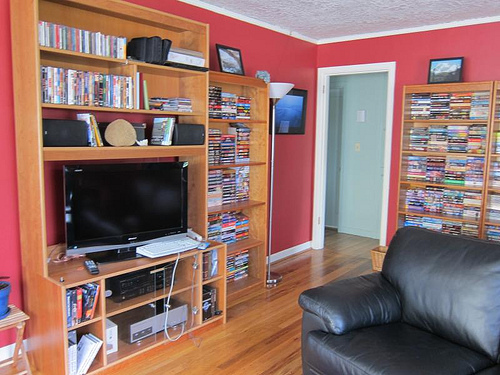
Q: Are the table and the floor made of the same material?
A: Yes, both the table and the floor are made of wood.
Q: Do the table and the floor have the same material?
A: Yes, both the table and the floor are made of wood.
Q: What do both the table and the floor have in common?
A: The material, both the table and the floor are wooden.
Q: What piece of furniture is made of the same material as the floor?
A: The table is made of the same material as the floor.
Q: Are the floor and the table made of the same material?
A: Yes, both the floor and the table are made of wood.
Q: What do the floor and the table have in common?
A: The material, both the floor and the table are wooden.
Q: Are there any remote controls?
A: Yes, there is a remote control.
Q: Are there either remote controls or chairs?
A: Yes, there is a remote control.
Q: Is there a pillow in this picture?
A: No, there are no pillows.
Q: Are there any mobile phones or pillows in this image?
A: No, there are no pillows or mobile phones.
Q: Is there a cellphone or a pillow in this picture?
A: No, there are no pillows or cell phones.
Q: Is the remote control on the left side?
A: Yes, the remote control is on the left of the image.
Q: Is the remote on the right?
A: No, the remote is on the left of the image.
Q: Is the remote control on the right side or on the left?
A: The remote control is on the left of the image.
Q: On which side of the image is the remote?
A: The remote is on the left of the image.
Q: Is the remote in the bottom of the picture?
A: Yes, the remote is in the bottom of the image.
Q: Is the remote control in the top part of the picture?
A: No, the remote control is in the bottom of the image.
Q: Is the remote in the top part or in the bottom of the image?
A: The remote is in the bottom of the image.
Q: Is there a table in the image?
A: Yes, there is a table.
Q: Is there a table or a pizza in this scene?
A: Yes, there is a table.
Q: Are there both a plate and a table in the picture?
A: No, there is a table but no plates.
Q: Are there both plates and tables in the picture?
A: No, there is a table but no plates.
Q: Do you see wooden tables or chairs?
A: Yes, there is a wood table.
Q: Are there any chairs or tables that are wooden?
A: Yes, the table is wooden.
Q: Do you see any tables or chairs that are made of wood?
A: Yes, the table is made of wood.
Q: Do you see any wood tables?
A: Yes, there is a wood table.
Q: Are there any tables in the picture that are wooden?
A: Yes, there is a table that is wooden.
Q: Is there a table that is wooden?
A: Yes, there is a table that is wooden.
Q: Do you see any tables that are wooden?
A: Yes, there is a table that is wooden.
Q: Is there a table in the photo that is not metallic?
A: Yes, there is a wooden table.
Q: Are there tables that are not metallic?
A: Yes, there is a wooden table.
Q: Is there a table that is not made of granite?
A: Yes, there is a table that is made of wood.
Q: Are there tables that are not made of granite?
A: Yes, there is a table that is made of wood.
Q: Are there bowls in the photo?
A: No, there are no bowls.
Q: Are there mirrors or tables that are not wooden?
A: No, there is a table but it is wooden.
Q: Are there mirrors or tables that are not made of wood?
A: No, there is a table but it is made of wood.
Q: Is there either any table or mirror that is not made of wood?
A: No, there is a table but it is made of wood.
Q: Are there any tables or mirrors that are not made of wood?
A: No, there is a table but it is made of wood.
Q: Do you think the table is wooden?
A: Yes, the table is wooden.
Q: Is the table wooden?
A: Yes, the table is wooden.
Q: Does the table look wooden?
A: Yes, the table is wooden.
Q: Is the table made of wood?
A: Yes, the table is made of wood.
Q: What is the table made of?
A: The table is made of wood.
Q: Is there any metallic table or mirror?
A: No, there is a table but it is wooden.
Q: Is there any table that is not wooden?
A: No, there is a table but it is wooden.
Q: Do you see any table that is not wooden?
A: No, there is a table but it is wooden.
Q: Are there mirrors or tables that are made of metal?
A: No, there is a table but it is made of wood.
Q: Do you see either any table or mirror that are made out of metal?
A: No, there is a table but it is made of wood.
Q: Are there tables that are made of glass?
A: No, there is a table but it is made of wood.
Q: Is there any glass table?
A: No, there is a table but it is made of wood.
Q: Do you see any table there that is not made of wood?
A: No, there is a table but it is made of wood.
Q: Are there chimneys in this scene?
A: No, there are no chimneys.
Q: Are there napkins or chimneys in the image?
A: No, there are no chimneys or napkins.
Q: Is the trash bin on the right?
A: Yes, the trash bin is on the right of the image.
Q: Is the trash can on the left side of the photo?
A: No, the trash can is on the right of the image.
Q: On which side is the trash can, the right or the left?
A: The trash can is on the right of the image.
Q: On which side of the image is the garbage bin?
A: The garbage bin is on the right of the image.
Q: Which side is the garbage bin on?
A: The garbage bin is on the right of the image.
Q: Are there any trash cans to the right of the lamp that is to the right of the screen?
A: Yes, there is a trash can to the right of the lamp.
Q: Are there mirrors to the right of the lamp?
A: No, there is a trash can to the right of the lamp.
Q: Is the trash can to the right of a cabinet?
A: No, the trash can is to the right of the lamp.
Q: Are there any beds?
A: No, there are no beds.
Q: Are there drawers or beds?
A: No, there are no beds or drawers.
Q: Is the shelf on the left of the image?
A: Yes, the shelf is on the left of the image.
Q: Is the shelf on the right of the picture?
A: No, the shelf is on the left of the image.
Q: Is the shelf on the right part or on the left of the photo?
A: The shelf is on the left of the image.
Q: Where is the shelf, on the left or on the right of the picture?
A: The shelf is on the left of the image.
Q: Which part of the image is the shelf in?
A: The shelf is on the left of the image.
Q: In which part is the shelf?
A: The shelf is on the left of the image.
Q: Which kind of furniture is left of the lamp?
A: The piece of furniture is a shelf.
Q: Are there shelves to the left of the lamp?
A: Yes, there is a shelf to the left of the lamp.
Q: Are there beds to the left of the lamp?
A: No, there is a shelf to the left of the lamp.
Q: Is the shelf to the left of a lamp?
A: Yes, the shelf is to the left of a lamp.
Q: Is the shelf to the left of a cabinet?
A: No, the shelf is to the left of a lamp.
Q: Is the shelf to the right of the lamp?
A: No, the shelf is to the left of the lamp.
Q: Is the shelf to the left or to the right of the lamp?
A: The shelf is to the left of the lamp.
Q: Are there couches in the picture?
A: Yes, there is a couch.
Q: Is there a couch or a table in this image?
A: Yes, there is a couch.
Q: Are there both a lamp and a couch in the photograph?
A: Yes, there are both a couch and a lamp.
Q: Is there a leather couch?
A: Yes, there is a couch that is made of leather.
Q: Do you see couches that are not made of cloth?
A: Yes, there is a couch that is made of leather.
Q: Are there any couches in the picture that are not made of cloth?
A: Yes, there is a couch that is made of leather.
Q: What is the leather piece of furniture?
A: The piece of furniture is a couch.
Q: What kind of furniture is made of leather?
A: The furniture is a couch.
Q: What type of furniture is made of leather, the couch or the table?
A: The couch is made of leather.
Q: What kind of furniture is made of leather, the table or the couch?
A: The couch is made of leather.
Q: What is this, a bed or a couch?
A: This is a couch.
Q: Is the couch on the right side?
A: Yes, the couch is on the right of the image.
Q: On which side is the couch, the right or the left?
A: The couch is on the right of the image.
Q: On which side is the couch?
A: The couch is on the right of the image.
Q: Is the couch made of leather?
A: Yes, the couch is made of leather.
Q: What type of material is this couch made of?
A: The couch is made of leather.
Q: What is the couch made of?
A: The couch is made of leather.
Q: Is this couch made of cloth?
A: No, the couch is made of leather.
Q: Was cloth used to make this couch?
A: No, the couch is made of leather.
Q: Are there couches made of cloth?
A: No, there is a couch but it is made of leather.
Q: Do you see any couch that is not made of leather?
A: No, there is a couch but it is made of leather.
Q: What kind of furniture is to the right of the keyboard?
A: The piece of furniture is a couch.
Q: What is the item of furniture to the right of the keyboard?
A: The piece of furniture is a couch.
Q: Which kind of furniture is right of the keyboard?
A: The piece of furniture is a couch.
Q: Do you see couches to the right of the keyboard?
A: Yes, there is a couch to the right of the keyboard.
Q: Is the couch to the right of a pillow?
A: No, the couch is to the right of the keyboard.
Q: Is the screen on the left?
A: Yes, the screen is on the left of the image.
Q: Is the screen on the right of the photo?
A: No, the screen is on the left of the image.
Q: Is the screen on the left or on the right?
A: The screen is on the left of the image.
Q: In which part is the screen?
A: The screen is on the left of the image.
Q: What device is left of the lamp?
A: The device is a screen.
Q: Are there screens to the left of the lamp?
A: Yes, there is a screen to the left of the lamp.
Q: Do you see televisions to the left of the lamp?
A: No, there is a screen to the left of the lamp.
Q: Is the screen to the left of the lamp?
A: Yes, the screen is to the left of the lamp.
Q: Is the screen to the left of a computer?
A: No, the screen is to the left of the lamp.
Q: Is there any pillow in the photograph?
A: No, there are no pillows.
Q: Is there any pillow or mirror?
A: No, there are no pillows or mirrors.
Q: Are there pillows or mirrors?
A: No, there are no pillows or mirrors.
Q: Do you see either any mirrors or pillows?
A: No, there are no pillows or mirrors.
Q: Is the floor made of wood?
A: Yes, the floor is made of wood.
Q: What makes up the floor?
A: The floor is made of wood.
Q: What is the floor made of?
A: The floor is made of wood.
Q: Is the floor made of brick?
A: No, the floor is made of wood.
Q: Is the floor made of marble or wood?
A: The floor is made of wood.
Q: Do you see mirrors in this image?
A: No, there are no mirrors.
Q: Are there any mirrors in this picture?
A: No, there are no mirrors.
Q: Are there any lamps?
A: Yes, there is a lamp.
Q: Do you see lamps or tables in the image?
A: Yes, there is a lamp.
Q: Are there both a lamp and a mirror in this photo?
A: No, there is a lamp but no mirrors.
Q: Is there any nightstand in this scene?
A: No, there are no nightstands.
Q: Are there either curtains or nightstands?
A: No, there are no nightstands or curtains.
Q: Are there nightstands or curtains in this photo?
A: No, there are no nightstands or curtains.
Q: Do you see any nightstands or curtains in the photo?
A: No, there are no nightstands or curtains.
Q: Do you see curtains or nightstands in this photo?
A: No, there are no nightstands or curtains.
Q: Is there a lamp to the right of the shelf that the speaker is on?
A: Yes, there is a lamp to the right of the shelf.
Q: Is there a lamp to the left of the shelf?
A: No, the lamp is to the right of the shelf.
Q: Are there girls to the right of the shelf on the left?
A: No, there is a lamp to the right of the shelf.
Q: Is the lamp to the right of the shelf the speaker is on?
A: Yes, the lamp is to the right of the shelf.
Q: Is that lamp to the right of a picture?
A: No, the lamp is to the right of the shelf.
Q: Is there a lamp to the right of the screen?
A: Yes, there is a lamp to the right of the screen.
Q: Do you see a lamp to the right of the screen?
A: Yes, there is a lamp to the right of the screen.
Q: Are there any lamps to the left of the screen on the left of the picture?
A: No, the lamp is to the right of the screen.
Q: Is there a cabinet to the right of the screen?
A: No, there is a lamp to the right of the screen.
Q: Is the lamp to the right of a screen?
A: Yes, the lamp is to the right of a screen.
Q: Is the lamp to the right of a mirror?
A: No, the lamp is to the right of a screen.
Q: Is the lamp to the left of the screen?
A: No, the lamp is to the right of the screen.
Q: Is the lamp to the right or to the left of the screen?
A: The lamp is to the right of the screen.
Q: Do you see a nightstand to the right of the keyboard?
A: No, there is a lamp to the right of the keyboard.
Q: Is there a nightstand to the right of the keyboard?
A: No, there is a lamp to the right of the keyboard.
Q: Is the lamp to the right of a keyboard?
A: Yes, the lamp is to the right of a keyboard.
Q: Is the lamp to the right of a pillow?
A: No, the lamp is to the right of a keyboard.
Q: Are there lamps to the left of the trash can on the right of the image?
A: Yes, there is a lamp to the left of the garbage bin.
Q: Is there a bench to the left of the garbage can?
A: No, there is a lamp to the left of the garbage can.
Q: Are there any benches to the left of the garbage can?
A: No, there is a lamp to the left of the garbage can.